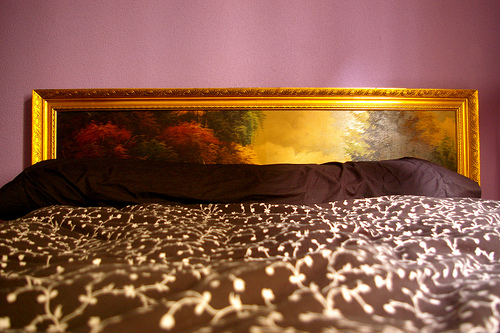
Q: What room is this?
A: It is a bedroom.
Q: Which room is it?
A: It is a bedroom.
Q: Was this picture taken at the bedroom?
A: Yes, it was taken in the bedroom.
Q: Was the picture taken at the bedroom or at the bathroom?
A: It was taken at the bedroom.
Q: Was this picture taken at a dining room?
A: No, the picture was taken in a bedroom.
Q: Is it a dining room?
A: No, it is a bedroom.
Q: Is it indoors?
A: Yes, it is indoors.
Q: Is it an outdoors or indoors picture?
A: It is indoors.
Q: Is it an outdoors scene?
A: No, it is indoors.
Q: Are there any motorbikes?
A: No, there are no motorbikes.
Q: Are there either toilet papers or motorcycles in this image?
A: No, there are no motorcycles or toilet papers.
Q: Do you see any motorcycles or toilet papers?
A: No, there are no motorcycles or toilet papers.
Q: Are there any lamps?
A: No, there are no lamps.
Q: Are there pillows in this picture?
A: Yes, there is a pillow.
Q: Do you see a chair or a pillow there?
A: Yes, there is a pillow.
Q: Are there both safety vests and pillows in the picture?
A: No, there is a pillow but no safety jackets.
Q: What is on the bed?
A: The pillow is on the bed.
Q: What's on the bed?
A: The pillow is on the bed.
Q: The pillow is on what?
A: The pillow is on the bed.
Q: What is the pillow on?
A: The pillow is on the bed.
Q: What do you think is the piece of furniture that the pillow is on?
A: The piece of furniture is a bed.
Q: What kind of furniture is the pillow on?
A: The pillow is on the bed.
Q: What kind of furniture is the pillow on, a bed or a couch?
A: The pillow is on a bed.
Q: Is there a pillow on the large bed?
A: Yes, there is a pillow on the bed.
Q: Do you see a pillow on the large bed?
A: Yes, there is a pillow on the bed.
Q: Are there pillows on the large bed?
A: Yes, there is a pillow on the bed.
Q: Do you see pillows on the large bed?
A: Yes, there is a pillow on the bed.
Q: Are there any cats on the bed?
A: No, there is a pillow on the bed.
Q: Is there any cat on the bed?
A: No, there is a pillow on the bed.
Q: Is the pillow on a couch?
A: No, the pillow is on a bed.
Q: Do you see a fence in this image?
A: No, there are no fences.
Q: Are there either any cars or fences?
A: No, there are no fences or cars.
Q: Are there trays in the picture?
A: No, there are no trays.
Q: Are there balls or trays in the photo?
A: No, there are no trays or balls.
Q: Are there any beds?
A: Yes, there is a bed.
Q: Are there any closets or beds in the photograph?
A: Yes, there is a bed.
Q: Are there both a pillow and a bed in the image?
A: Yes, there are both a bed and a pillow.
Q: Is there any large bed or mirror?
A: Yes, there is a large bed.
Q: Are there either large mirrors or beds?
A: Yes, there is a large bed.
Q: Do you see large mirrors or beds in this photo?
A: Yes, there is a large bed.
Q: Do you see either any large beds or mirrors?
A: Yes, there is a large bed.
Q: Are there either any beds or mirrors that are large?
A: Yes, the bed is large.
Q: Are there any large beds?
A: Yes, there is a large bed.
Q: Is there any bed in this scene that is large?
A: Yes, there is a bed that is large.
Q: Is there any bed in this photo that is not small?
A: Yes, there is a large bed.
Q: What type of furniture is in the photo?
A: The furniture is a bed.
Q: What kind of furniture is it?
A: The piece of furniture is a bed.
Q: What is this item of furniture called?
A: This is a bed.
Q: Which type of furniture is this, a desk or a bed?
A: This is a bed.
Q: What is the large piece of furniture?
A: The piece of furniture is a bed.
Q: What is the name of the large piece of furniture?
A: The piece of furniture is a bed.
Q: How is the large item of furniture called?
A: The piece of furniture is a bed.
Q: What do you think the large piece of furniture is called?
A: The piece of furniture is a bed.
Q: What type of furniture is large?
A: The furniture is a bed.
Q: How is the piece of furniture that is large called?
A: The piece of furniture is a bed.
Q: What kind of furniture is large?
A: The furniture is a bed.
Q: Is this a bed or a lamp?
A: This is a bed.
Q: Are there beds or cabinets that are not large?
A: No, there is a bed but it is large.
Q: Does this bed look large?
A: Yes, the bed is large.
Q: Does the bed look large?
A: Yes, the bed is large.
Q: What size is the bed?
A: The bed is large.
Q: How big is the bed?
A: The bed is large.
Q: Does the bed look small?
A: No, the bed is large.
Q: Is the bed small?
A: No, the bed is large.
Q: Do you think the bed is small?
A: No, the bed is large.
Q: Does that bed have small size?
A: No, the bed is large.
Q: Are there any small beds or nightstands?
A: No, there is a bed but it is large.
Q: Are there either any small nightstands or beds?
A: No, there is a bed but it is large.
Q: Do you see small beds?
A: No, there is a bed but it is large.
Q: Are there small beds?
A: No, there is a bed but it is large.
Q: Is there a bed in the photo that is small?
A: No, there is a bed but it is large.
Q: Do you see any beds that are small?
A: No, there is a bed but it is large.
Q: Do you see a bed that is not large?
A: No, there is a bed but it is large.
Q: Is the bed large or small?
A: The bed is large.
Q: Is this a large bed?
A: Yes, this is a large bed.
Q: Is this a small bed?
A: No, this is a large bed.